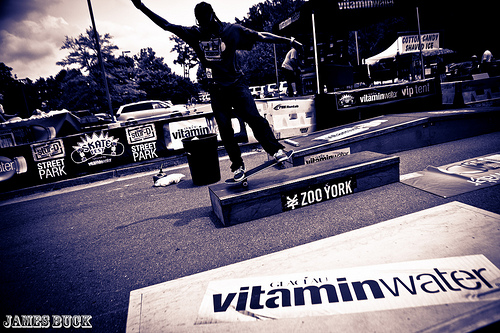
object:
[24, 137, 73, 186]
banner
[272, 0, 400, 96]
tent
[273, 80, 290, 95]
cars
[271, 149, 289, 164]
sneaker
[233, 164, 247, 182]
sneaker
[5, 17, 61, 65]
clouds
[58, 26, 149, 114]
trees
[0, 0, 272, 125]
background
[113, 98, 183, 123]
car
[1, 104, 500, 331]
road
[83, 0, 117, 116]
post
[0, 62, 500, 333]
ground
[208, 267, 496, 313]
logo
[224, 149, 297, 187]
skate board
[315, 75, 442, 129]
stands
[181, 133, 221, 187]
bin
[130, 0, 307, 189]
man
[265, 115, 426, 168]
ramp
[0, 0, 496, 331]
area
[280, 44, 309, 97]
people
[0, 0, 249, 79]
sky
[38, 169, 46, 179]
words